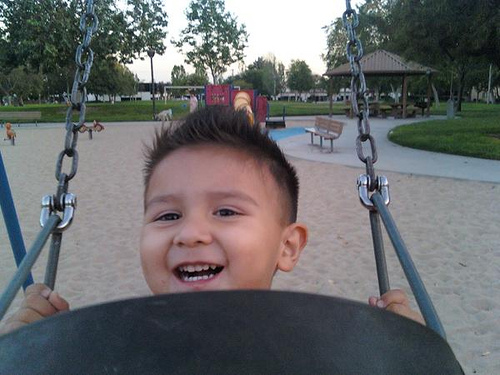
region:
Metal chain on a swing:
[339, 0, 391, 207]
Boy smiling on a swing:
[126, 110, 310, 295]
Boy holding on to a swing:
[363, 287, 434, 325]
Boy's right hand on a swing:
[0, 280, 72, 333]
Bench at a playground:
[304, 115, 344, 149]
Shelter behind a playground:
[314, 48, 434, 118]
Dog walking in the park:
[149, 107, 174, 122]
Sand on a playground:
[1, 122, 496, 373]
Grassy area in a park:
[383, 112, 494, 159]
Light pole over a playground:
[144, 45, 161, 120]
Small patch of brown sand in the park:
[420, 221, 445, 247]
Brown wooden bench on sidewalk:
[306, 111, 341, 148]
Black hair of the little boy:
[196, 109, 245, 134]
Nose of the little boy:
[173, 224, 216, 246]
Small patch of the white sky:
[258, 3, 299, 28]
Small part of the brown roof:
[378, 50, 395, 65]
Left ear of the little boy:
[281, 222, 310, 274]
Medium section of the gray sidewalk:
[409, 151, 441, 176]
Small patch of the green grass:
[121, 107, 136, 120]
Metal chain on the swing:
[344, 57, 379, 119]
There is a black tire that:
[315, 299, 340, 362]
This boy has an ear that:
[291, 215, 313, 306]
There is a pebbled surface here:
[458, 215, 483, 294]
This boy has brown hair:
[221, 135, 236, 163]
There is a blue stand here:
[4, 216, 31, 249]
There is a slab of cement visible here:
[406, 151, 416, 174]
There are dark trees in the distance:
[36, 31, 63, 77]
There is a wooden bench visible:
[311, 107, 338, 157]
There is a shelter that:
[384, 59, 395, 81]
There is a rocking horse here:
[2, 120, 18, 153]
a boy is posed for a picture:
[108, 111, 313, 283]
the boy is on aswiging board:
[111, 136, 370, 329]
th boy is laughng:
[143, 89, 380, 324]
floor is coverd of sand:
[412, 202, 486, 304]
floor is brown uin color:
[455, 200, 482, 322]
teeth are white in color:
[155, 259, 239, 285]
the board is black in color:
[98, 278, 366, 370]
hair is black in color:
[173, 98, 302, 184]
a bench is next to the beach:
[304, 101, 351, 152]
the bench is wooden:
[304, 82, 348, 154]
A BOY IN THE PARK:
[94, 37, 494, 366]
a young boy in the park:
[100, 62, 424, 359]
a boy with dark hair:
[147, 66, 358, 303]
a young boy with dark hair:
[114, 81, 428, 343]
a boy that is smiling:
[85, 77, 335, 368]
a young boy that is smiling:
[130, 76, 365, 283]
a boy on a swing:
[53, 56, 365, 341]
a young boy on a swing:
[66, 31, 361, 363]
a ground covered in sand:
[43, 127, 290, 283]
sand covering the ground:
[58, 120, 242, 238]